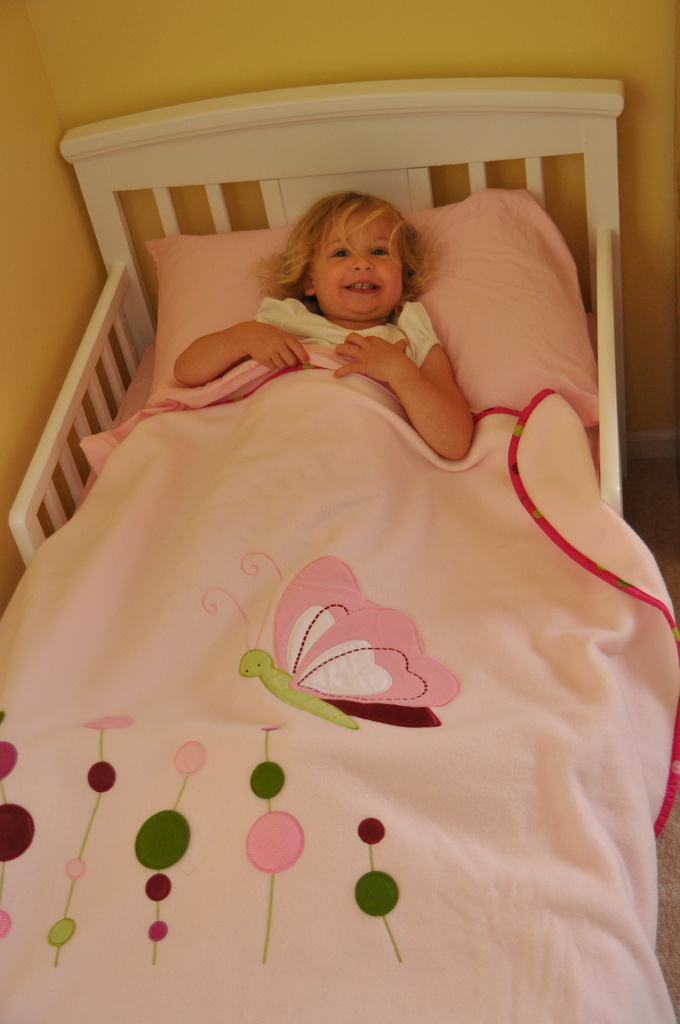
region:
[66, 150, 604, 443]
the pillow is pink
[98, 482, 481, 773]
a butterfly is on the blanket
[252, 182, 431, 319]
the little girl's hair is blonde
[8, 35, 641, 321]
the bed frame is white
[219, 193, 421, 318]
the girl is smiling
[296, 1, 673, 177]
the wall is yellow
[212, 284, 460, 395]
the shirt is white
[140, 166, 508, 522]
the girl is laying down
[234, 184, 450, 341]
the eyes are open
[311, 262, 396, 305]
the teeth are showing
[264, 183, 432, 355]
A young white girl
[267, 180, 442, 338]
A young girl smiling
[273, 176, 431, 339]
A young Caucasian female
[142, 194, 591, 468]
A young girl tucked in bed.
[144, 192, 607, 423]
A pink pillow of a young girl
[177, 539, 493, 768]
A butterfly design sown into a sheet.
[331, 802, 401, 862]
A small maroon circle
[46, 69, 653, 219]
A small wooden headboard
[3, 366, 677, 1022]
pink and green butterfly on the blanket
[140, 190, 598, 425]
pillow is pink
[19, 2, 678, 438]
wall is bright yellow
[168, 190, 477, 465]
little girl is blonde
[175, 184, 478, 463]
little girl wearing a white shirt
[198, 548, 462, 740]
butterfly has green body and pink wings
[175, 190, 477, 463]
little girl is smiling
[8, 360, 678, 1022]
blanket is pink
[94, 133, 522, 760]
Little girl in a toddler bed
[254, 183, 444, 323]
Little girl with blonde hair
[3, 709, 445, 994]
Several multi-colored flowers on pink blanket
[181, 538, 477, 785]
Butterfly on little girl's pink blanket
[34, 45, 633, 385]
White headboard on toddler bed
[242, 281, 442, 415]
Short sleeved white t-shirt worn by little girl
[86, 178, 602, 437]
Pink pillow being laid on by little girl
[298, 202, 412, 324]
Smiling face of cute little girl in toddler bed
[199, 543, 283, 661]
Antennae on butterfly on blanket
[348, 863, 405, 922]
a green circular design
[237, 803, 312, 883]
a pink circular design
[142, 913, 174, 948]
a small dark pink circular design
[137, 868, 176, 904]
a maroon circular design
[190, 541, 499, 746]
a butterfly design on a cloth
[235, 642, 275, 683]
the head of a butterfly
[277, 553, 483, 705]
the wings of a butterfly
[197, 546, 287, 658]
the antenna on the head of a butterfly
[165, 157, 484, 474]
a white child tucked in bed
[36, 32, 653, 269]
headboard of a child's bed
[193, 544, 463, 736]
pink and maroon butterfly with a green body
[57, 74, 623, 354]
white slats on a headboard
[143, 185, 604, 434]
pink pillowcase on a soft pillow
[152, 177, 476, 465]
Blonde girl lying in bed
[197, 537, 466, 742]
Butterfly on the blanket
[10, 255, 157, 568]
White post on side of bed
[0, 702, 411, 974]
Flower appliques on blanket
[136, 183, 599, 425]
Pink pillow under girl's head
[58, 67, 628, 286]
White headboard on bed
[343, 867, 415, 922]
Green circle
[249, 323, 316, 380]
GIrl's right hand holding the blanket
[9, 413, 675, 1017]
Pink blanket on the bed